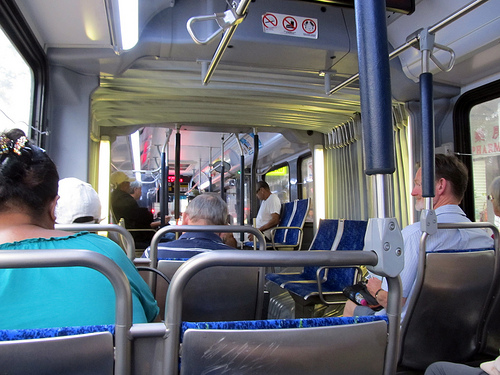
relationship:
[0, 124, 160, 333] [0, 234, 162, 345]
lady wearing shirt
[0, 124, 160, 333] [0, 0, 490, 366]
lady sitting in train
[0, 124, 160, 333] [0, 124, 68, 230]
lady has hair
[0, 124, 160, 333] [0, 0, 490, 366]
lady sitting on a train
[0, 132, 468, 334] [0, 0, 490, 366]
commuters are riding i a train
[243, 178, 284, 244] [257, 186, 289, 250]
man wearing shirt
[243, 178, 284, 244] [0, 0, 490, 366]
man on a train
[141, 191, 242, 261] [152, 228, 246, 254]
man wearing shirt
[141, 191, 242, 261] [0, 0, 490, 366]
man on a train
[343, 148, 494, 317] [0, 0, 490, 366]
man on a train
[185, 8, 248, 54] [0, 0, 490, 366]
handrail on a train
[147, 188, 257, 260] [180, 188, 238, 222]
man has hair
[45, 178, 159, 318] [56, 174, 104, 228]
person wearing hat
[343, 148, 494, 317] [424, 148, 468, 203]
man has hair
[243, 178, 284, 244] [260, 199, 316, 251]
man sitting on a bus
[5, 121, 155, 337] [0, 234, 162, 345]
woman wearing shirt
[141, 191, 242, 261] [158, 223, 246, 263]
man wearing shirt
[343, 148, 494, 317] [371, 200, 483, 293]
man wearing shirt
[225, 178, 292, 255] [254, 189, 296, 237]
man wearing shirt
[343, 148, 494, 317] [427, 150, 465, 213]
man has hair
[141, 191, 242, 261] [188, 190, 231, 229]
man has hair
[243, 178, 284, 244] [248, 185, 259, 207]
man wearing a white shirt and glasses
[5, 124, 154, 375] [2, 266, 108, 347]
lady with brown hair and blue shirt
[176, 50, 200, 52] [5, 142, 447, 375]
safety handle for a bus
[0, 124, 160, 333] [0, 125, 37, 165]
lady with hair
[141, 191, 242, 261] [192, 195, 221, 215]
man sitting on bus has grey hair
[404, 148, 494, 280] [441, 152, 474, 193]
man sitting on bus has brown hair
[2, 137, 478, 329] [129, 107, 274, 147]
group of people using mass transit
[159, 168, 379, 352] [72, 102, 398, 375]
two empty blue seats on bus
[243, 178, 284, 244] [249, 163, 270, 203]
man with a hat standing on bus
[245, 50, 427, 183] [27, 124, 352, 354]
drapes dividing an area on mass transit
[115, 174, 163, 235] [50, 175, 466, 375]
two people sitting together on mass transit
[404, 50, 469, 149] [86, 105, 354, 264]
hand rail on mass transit